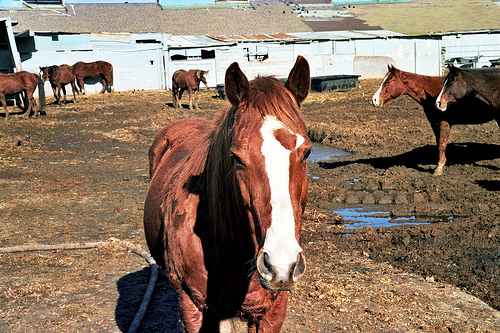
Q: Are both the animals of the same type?
A: Yes, all the animals are horses.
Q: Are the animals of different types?
A: No, all the animals are horses.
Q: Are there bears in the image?
A: No, there are no bears.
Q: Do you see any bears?
A: No, there are no bears.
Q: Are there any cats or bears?
A: No, there are no bears or cats.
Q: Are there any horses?
A: Yes, there is a horse.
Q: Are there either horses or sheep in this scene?
A: Yes, there is a horse.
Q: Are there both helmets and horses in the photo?
A: No, there is a horse but no helmets.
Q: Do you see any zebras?
A: No, there are no zebras.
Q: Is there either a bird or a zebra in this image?
A: No, there are no zebras or birds.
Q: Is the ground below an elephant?
A: No, the ground is below a horse.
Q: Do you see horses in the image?
A: Yes, there is a horse.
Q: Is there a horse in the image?
A: Yes, there is a horse.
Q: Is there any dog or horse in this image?
A: Yes, there is a horse.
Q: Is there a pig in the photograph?
A: No, there are no pigs.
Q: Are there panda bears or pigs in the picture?
A: No, there are no pigs or panda bears.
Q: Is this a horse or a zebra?
A: This is a horse.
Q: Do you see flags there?
A: No, there are no flags.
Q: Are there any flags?
A: No, there are no flags.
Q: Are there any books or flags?
A: No, there are no flags or books.